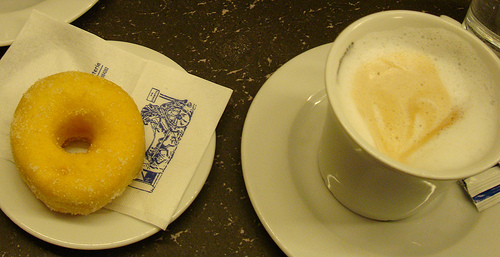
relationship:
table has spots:
[0, 2, 499, 255] [1, 1, 469, 255]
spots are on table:
[1, 1, 469, 255] [0, 2, 499, 255]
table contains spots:
[0, 2, 499, 255] [1, 1, 469, 255]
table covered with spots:
[0, 2, 499, 255] [1, 1, 469, 255]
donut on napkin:
[9, 71, 146, 215] [1, 8, 235, 233]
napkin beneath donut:
[1, 8, 235, 233] [9, 71, 146, 215]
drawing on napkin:
[89, 61, 197, 194] [1, 8, 235, 233]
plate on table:
[0, 40, 217, 250] [0, 2, 499, 255]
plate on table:
[240, 42, 499, 256] [0, 2, 499, 255]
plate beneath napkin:
[0, 40, 217, 250] [1, 8, 235, 233]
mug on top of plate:
[315, 9, 499, 223] [240, 42, 499, 256]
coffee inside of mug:
[338, 28, 500, 171] [315, 9, 499, 223]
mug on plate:
[315, 9, 499, 223] [240, 42, 499, 256]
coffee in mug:
[338, 28, 500, 171] [315, 9, 499, 223]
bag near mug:
[459, 163, 499, 212] [315, 9, 499, 223]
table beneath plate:
[0, 2, 499, 255] [239, 39, 500, 256]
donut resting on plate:
[9, 71, 146, 215] [0, 40, 217, 250]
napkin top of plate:
[1, 8, 235, 233] [0, 40, 217, 250]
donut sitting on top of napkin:
[9, 71, 146, 215] [1, 8, 235, 233]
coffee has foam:
[338, 28, 500, 171] [333, 28, 498, 172]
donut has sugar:
[9, 71, 146, 215] [11, 71, 146, 213]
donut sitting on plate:
[9, 71, 146, 215] [0, 40, 217, 250]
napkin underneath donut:
[1, 8, 235, 233] [9, 71, 146, 215]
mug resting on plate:
[315, 9, 499, 223] [240, 42, 499, 256]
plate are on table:
[239, 39, 500, 256] [0, 2, 499, 255]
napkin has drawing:
[1, 8, 235, 233] [89, 61, 197, 194]